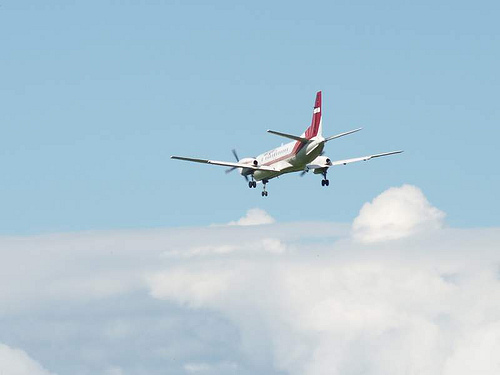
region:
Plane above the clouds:
[142, 71, 417, 213]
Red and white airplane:
[121, 58, 425, 211]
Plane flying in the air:
[130, 65, 427, 220]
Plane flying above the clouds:
[122, 48, 430, 199]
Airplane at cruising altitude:
[161, 86, 429, 207]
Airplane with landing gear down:
[143, 76, 416, 217]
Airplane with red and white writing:
[161, 64, 419, 200]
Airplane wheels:
[308, 162, 342, 194]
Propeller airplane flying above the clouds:
[160, 81, 409, 224]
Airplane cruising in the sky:
[151, 58, 430, 226]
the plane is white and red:
[171, 87, 406, 192]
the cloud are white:
[1, 184, 499, 373]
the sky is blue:
[0, 0, 499, 229]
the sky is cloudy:
[0, 0, 498, 374]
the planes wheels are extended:
[246, 177, 330, 196]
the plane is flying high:
[172, 86, 402, 192]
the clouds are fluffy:
[7, 182, 497, 372]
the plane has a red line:
[173, 90, 403, 196]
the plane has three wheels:
[248, 176, 330, 197]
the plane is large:
[171, 90, 406, 196]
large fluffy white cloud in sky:
[363, 181, 440, 262]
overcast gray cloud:
[49, 225, 232, 250]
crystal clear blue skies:
[71, 97, 198, 129]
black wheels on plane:
[259, 187, 281, 201]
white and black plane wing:
[154, 150, 251, 178]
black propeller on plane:
[224, 143, 256, 182]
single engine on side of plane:
[234, 156, 266, 176]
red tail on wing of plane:
[298, 86, 335, 150]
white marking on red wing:
[297, 101, 328, 121]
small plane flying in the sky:
[161, 84, 411, 239]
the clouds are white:
[76, 279, 313, 321]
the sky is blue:
[61, 134, 136, 190]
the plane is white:
[161, 90, 401, 185]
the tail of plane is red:
[311, 88, 322, 133]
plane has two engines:
[168, 90, 405, 192]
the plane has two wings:
[170, 91, 403, 196]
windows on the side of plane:
[266, 152, 288, 159]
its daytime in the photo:
[2, 4, 494, 370]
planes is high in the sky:
[180, 90, 407, 186]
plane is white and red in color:
[163, 85, 410, 187]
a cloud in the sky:
[346, 173, 445, 242]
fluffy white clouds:
[1, 210, 495, 373]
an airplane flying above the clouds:
[166, 88, 405, 193]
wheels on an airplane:
[320, 178, 334, 186]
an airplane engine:
[236, 158, 261, 178]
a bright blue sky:
[1, 2, 498, 227]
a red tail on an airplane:
[290, 92, 334, 133]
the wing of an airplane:
[166, 152, 281, 175]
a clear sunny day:
[1, 3, 498, 233]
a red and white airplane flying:
[166, 89, 405, 196]